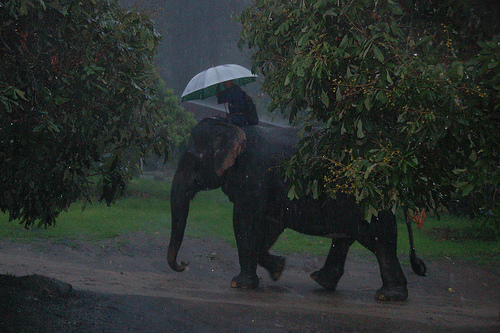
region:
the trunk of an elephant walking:
[166, 154, 188, 268]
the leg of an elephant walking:
[227, 198, 257, 288]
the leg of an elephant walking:
[252, 200, 288, 281]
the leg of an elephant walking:
[307, 226, 349, 287]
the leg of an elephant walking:
[364, 210, 406, 302]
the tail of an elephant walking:
[400, 196, 427, 278]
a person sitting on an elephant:
[215, 77, 255, 124]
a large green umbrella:
[181, 60, 253, 97]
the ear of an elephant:
[210, 118, 249, 178]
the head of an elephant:
[173, 110, 227, 192]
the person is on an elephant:
[181, 66, 263, 121]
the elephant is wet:
[166, 118, 431, 303]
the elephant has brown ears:
[210, 122, 246, 172]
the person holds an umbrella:
[180, 63, 256, 105]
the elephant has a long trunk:
[173, 185, 186, 277]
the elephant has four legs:
[232, 207, 412, 309]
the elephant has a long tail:
[398, 200, 427, 275]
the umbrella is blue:
[180, 59, 254, 97]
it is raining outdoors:
[1, 1, 499, 330]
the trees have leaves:
[0, 0, 495, 232]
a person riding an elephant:
[163, 57, 427, 307]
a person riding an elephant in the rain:
[157, 48, 427, 315]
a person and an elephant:
[157, 55, 435, 305]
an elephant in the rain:
[153, 108, 432, 305]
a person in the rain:
[174, 55, 274, 127]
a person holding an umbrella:
[176, 58, 269, 125]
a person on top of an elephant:
[162, 57, 295, 310]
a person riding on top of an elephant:
[160, 51, 281, 292]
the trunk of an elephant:
[165, 144, 190, 278]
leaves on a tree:
[242, 22, 499, 237]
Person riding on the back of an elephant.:
[165, 61, 428, 302]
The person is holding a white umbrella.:
[180, 60, 258, 167]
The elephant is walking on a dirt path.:
[0, 235, 495, 320]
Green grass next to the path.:
[0, 170, 495, 255]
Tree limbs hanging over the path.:
[0, 0, 497, 225]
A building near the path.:
[105, 93, 298, 173]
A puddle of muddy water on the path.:
[0, 250, 165, 307]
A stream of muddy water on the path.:
[0, 250, 491, 325]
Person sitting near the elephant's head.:
[211, 70, 259, 175]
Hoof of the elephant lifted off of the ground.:
[261, 252, 289, 283]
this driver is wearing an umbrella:
[163, 54, 273, 135]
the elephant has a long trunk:
[144, 116, 226, 276]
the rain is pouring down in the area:
[157, 22, 449, 307]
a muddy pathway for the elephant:
[14, 222, 492, 331]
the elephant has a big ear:
[195, 119, 252, 182]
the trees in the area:
[11, 9, 173, 237]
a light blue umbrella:
[157, 5, 257, 100]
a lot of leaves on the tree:
[259, 9, 489, 215]